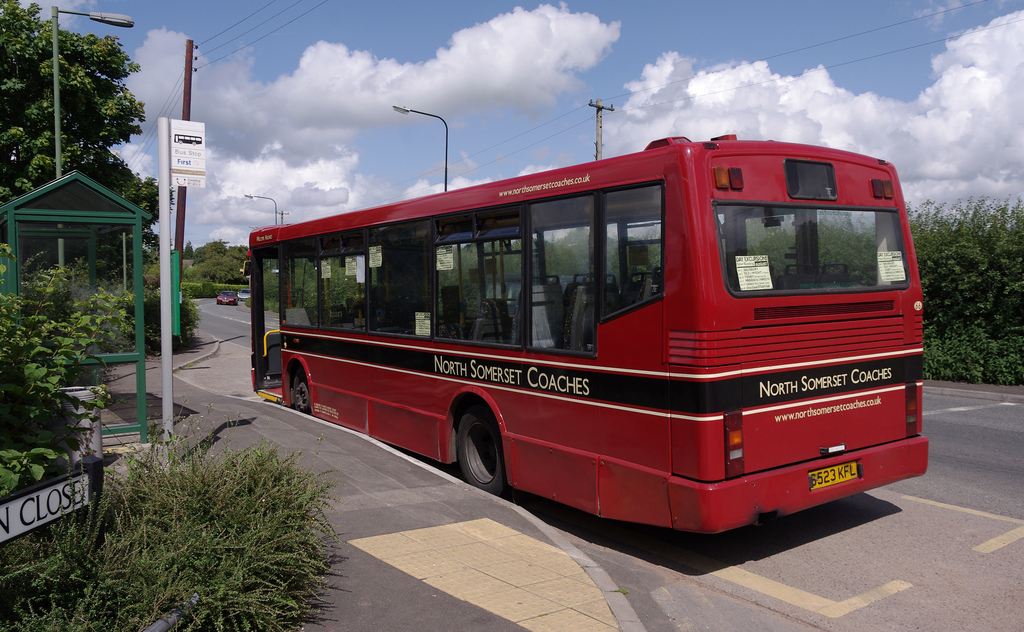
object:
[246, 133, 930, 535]
bus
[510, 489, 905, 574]
bus shadow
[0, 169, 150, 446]
bus stop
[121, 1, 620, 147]
cloud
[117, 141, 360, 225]
cloud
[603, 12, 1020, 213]
cloud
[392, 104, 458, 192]
street light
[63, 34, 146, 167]
street light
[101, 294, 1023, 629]
pavement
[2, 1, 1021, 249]
sky